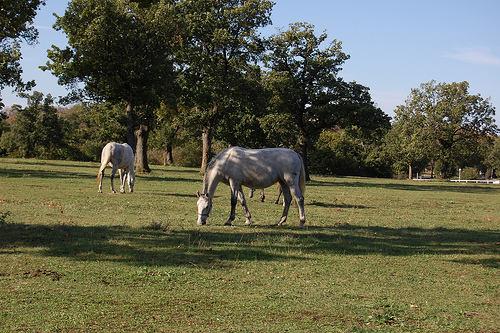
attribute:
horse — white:
[196, 143, 306, 224]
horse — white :
[193, 140, 314, 227]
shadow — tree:
[0, 209, 499, 270]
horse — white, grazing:
[195, 144, 312, 231]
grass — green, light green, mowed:
[2, 156, 499, 331]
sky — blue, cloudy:
[260, 0, 499, 121]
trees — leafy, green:
[2, 0, 499, 177]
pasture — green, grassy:
[0, 155, 499, 332]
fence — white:
[407, 164, 499, 188]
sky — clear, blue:
[0, 1, 499, 120]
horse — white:
[98, 136, 141, 191]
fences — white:
[411, 169, 481, 188]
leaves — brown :
[21, 110, 122, 136]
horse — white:
[193, 138, 313, 234]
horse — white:
[186, 143, 310, 230]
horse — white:
[87, 120, 145, 203]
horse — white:
[195, 135, 315, 230]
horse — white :
[190, 144, 313, 242]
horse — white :
[186, 129, 319, 226]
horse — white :
[153, 133, 321, 225]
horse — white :
[176, 144, 316, 228]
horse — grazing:
[97, 140, 150, 202]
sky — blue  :
[1, 0, 495, 139]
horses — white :
[96, 130, 316, 230]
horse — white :
[93, 137, 143, 199]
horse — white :
[189, 133, 309, 237]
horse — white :
[85, 130, 156, 195]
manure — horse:
[19, 260, 70, 285]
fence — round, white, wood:
[411, 160, 497, 187]